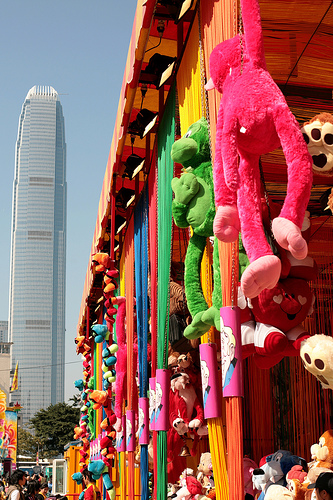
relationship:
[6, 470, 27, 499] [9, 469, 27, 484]
man with hair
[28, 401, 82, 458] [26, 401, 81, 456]
tree with leaves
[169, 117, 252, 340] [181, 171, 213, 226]
monkey holding chest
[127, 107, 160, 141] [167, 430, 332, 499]
light above stand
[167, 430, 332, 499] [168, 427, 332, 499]
stand selling stuffed animals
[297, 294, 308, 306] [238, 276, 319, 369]
heart on stuffed animal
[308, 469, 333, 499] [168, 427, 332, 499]
person looking at stuffed animals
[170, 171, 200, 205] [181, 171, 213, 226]
paw on chest